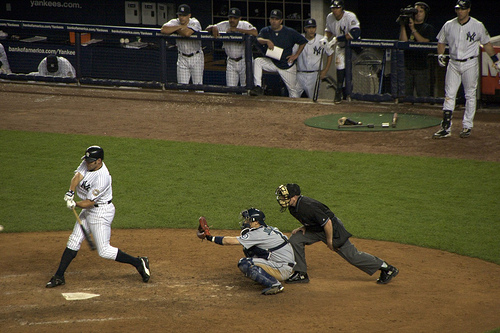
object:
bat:
[64, 195, 98, 252]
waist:
[246, 226, 294, 263]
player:
[290, 16, 335, 100]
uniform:
[211, 20, 256, 90]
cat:
[84, 31, 153, 84]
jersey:
[73, 159, 114, 206]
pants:
[64, 204, 119, 264]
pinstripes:
[65, 207, 118, 259]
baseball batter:
[44, 144, 153, 289]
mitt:
[195, 215, 212, 241]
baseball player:
[158, 3, 206, 94]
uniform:
[208, 20, 254, 85]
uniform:
[160, 17, 206, 94]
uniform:
[435, 17, 490, 130]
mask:
[273, 181, 292, 215]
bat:
[312, 43, 327, 102]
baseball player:
[271, 180, 403, 286]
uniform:
[286, 196, 388, 277]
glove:
[196, 216, 214, 244]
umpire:
[273, 181, 400, 287]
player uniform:
[320, 10, 360, 88]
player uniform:
[431, 0, 497, 141]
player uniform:
[157, 11, 207, 95]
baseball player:
[204, 7, 259, 93]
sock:
[53, 246, 79, 276]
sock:
[114, 249, 143, 269]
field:
[0, 75, 498, 330]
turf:
[172, 151, 254, 178]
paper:
[264, 45, 285, 61]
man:
[247, 9, 311, 98]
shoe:
[135, 256, 151, 283]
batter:
[42, 143, 150, 291]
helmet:
[81, 145, 105, 163]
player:
[194, 206, 297, 297]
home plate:
[61, 291, 101, 301]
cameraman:
[391, 0, 437, 105]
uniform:
[37, 56, 73, 79]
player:
[32, 45, 76, 81]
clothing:
[285, 194, 353, 250]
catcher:
[195, 206, 297, 297]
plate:
[57, 291, 101, 301]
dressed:
[284, 195, 386, 277]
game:
[42, 144, 400, 298]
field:
[125, 127, 273, 199]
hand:
[195, 222, 209, 241]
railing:
[74, 25, 180, 89]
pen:
[55, 23, 156, 93]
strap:
[278, 231, 291, 249]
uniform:
[231, 225, 297, 285]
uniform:
[285, 36, 334, 101]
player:
[319, 3, 365, 105]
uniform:
[320, 11, 360, 90]